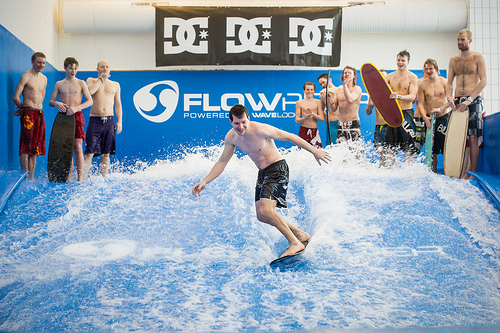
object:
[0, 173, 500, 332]
tarp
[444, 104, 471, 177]
surfboard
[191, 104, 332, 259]
man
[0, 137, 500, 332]
wave pool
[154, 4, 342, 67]
banner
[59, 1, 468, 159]
wall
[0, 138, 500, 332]
wave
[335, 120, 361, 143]
swimming trunks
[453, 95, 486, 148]
swimming trunks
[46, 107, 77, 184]
surfboard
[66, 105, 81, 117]
boys hands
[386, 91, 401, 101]
boys hands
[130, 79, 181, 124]
design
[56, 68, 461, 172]
back wall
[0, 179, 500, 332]
wave ramp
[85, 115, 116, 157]
shorts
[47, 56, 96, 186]
man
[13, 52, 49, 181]
waiting boy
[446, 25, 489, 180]
waiting boy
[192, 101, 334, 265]
surf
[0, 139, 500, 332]
pool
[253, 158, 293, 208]
shorts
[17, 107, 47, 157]
short